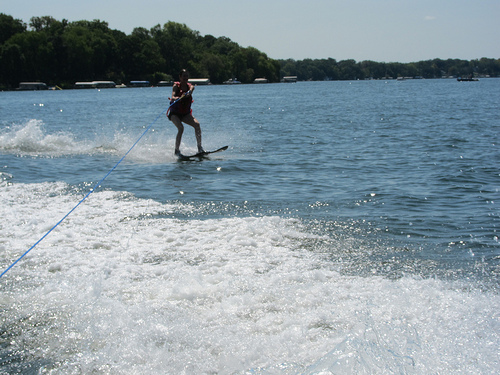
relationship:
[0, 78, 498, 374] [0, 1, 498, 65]
water beneath sky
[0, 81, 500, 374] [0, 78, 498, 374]
ripple on surface of water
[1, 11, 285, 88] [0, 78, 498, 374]
trees behind water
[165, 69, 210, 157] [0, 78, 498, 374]
person on top of water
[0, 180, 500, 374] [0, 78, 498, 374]
wake in water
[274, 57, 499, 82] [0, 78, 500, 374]
trees alongside lake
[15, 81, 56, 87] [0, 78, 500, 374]
dock alongside lake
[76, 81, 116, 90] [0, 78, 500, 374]
dock alongside lake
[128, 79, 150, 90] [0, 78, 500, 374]
dock alongside lake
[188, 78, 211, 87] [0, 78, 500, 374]
dock alongside lake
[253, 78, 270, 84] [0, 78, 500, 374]
dock alongside lake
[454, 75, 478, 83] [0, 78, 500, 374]
boat sitting in lake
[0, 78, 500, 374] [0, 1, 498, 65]
lake under sky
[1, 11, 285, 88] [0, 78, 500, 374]
trees behind lake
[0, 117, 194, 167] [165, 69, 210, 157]
wake behind person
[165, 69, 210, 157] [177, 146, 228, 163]
woman on top of skis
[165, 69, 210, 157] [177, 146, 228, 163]
person standing on skis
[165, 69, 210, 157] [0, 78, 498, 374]
person standing on water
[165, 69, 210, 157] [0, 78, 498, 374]
person skiing on water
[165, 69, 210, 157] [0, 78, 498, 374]
person on surface of water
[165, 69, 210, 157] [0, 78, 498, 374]
person riding on water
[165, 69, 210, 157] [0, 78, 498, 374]
person being pulled on water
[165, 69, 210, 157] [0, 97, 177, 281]
person holding cord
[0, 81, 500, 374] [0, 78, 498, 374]
ripple splashing in water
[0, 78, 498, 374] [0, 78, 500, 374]
water inside lake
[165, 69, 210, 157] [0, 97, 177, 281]
person pulling cord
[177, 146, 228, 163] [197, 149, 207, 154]
skis under foot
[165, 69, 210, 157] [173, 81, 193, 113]
person wearing vest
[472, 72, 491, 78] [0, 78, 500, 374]
house across lake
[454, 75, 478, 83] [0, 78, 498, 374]
boat floating in water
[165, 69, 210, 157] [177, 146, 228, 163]
person wearing skis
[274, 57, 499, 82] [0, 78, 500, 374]
trees across lake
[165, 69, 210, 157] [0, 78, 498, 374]
person standing in water